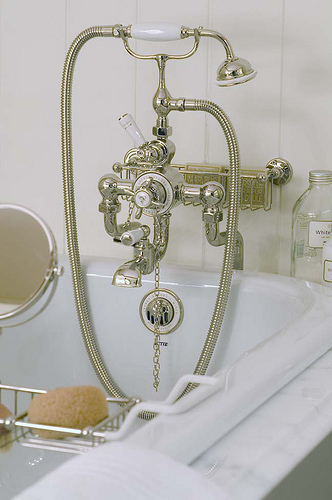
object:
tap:
[116, 221, 155, 251]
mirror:
[1, 205, 59, 327]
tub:
[0, 244, 331, 498]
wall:
[0, 1, 330, 277]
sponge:
[25, 384, 113, 437]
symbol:
[137, 194, 148, 207]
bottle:
[287, 168, 331, 280]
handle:
[115, 112, 156, 163]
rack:
[0, 371, 225, 450]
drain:
[142, 285, 182, 334]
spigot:
[117, 17, 257, 91]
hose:
[63, 25, 242, 423]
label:
[307, 219, 330, 275]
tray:
[157, 153, 298, 210]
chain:
[149, 336, 164, 388]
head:
[213, 53, 258, 89]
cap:
[305, 168, 331, 184]